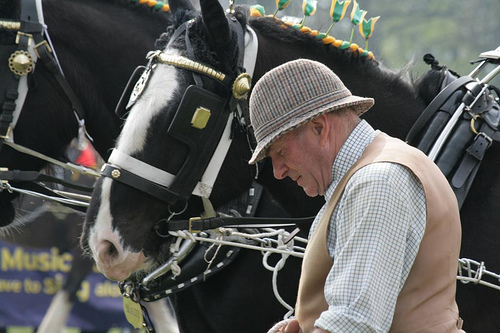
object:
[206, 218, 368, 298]
rope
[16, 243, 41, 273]
letters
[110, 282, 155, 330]
yellow tag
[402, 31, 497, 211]
sadle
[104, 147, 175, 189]
strap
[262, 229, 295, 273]
knot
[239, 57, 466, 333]
man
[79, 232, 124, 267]
nose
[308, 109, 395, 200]
ground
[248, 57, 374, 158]
cap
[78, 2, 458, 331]
horse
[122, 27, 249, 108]
something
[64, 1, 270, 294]
head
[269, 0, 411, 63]
mane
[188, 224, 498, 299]
rope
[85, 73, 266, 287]
fur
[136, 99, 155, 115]
spot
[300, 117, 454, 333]
shirt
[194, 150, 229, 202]
belt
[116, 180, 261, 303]
strap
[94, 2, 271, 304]
harness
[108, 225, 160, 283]
mouth